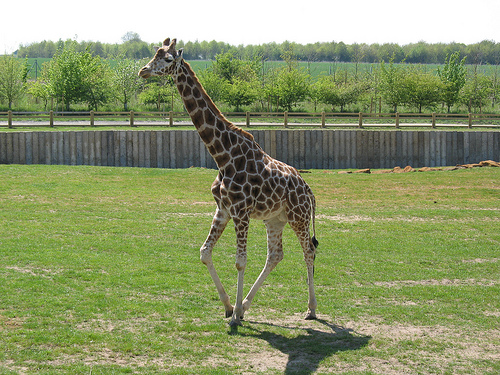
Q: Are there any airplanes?
A: No, there are no airplanes.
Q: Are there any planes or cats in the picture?
A: No, there are no planes or cats.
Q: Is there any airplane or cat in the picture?
A: No, there are no airplanes or cats.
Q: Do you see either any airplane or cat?
A: No, there are no airplanes or cats.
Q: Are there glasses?
A: No, there are no glasses.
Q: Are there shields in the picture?
A: No, there are no shields.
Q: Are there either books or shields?
A: No, there are no shields or books.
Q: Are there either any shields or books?
A: No, there are no shields or books.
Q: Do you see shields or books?
A: No, there are no shields or books.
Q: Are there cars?
A: No, there are no cars.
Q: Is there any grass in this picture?
A: Yes, there is grass.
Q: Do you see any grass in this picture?
A: Yes, there is grass.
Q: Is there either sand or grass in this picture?
A: Yes, there is grass.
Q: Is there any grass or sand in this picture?
A: Yes, there is grass.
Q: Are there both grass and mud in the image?
A: No, there is grass but no mud.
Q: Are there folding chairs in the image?
A: No, there are no folding chairs.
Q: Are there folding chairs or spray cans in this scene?
A: No, there are no folding chairs or spray cans.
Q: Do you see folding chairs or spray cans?
A: No, there are no folding chairs or spray cans.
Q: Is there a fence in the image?
A: Yes, there is a fence.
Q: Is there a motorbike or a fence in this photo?
A: Yes, there is a fence.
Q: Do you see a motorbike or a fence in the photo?
A: Yes, there is a fence.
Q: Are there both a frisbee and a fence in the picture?
A: No, there is a fence but no frisbees.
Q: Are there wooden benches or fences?
A: Yes, there is a wood fence.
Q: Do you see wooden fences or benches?
A: Yes, there is a wood fence.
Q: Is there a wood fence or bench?
A: Yes, there is a wood fence.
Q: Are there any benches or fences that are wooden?
A: Yes, the fence is wooden.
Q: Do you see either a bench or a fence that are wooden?
A: Yes, the fence is wooden.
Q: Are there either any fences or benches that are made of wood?
A: Yes, the fence is made of wood.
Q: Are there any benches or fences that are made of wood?
A: Yes, the fence is made of wood.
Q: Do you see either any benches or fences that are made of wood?
A: Yes, the fence is made of wood.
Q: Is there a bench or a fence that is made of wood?
A: Yes, the fence is made of wood.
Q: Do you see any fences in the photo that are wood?
A: Yes, there is a wood fence.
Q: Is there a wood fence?
A: Yes, there is a wood fence.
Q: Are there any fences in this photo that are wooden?
A: Yes, there is a fence that is wooden.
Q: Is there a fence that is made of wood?
A: Yes, there is a fence that is made of wood.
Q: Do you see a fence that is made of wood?
A: Yes, there is a fence that is made of wood.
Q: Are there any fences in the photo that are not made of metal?
A: Yes, there is a fence that is made of wood.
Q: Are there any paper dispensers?
A: No, there are no paper dispensers.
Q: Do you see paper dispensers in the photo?
A: No, there are no paper dispensers.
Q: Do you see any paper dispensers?
A: No, there are no paper dispensers.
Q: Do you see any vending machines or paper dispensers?
A: No, there are no paper dispensers or vending machines.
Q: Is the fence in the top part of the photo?
A: Yes, the fence is in the top of the image.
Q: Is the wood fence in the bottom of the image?
A: No, the fence is in the top of the image.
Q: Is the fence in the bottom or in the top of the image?
A: The fence is in the top of the image.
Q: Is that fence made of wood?
A: Yes, the fence is made of wood.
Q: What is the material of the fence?
A: The fence is made of wood.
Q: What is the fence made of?
A: The fence is made of wood.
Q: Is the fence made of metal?
A: No, the fence is made of wood.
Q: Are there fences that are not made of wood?
A: No, there is a fence but it is made of wood.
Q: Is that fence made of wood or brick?
A: The fence is made of wood.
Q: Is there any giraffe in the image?
A: Yes, there is a giraffe.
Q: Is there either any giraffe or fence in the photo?
A: Yes, there is a giraffe.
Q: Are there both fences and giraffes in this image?
A: Yes, there are both a giraffe and a fence.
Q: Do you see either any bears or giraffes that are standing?
A: Yes, the giraffe is standing.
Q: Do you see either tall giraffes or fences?
A: Yes, there is a tall giraffe.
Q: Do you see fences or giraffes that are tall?
A: Yes, the giraffe is tall.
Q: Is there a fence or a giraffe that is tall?
A: Yes, the giraffe is tall.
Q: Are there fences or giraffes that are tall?
A: Yes, the giraffe is tall.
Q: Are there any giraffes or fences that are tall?
A: Yes, the giraffe is tall.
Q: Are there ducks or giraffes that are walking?
A: Yes, the giraffe is walking.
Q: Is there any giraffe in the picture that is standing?
A: Yes, there is a giraffe that is standing.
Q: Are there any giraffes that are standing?
A: Yes, there is a giraffe that is standing.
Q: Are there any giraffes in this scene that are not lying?
A: Yes, there is a giraffe that is standing.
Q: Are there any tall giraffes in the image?
A: Yes, there is a tall giraffe.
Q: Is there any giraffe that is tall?
A: Yes, there is a giraffe that is tall.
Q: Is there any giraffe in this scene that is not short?
A: Yes, there is a tall giraffe.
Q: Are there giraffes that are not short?
A: Yes, there is a tall giraffe.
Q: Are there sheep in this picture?
A: No, there are no sheep.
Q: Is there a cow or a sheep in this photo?
A: No, there are no sheep or cows.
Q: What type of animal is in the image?
A: The animal is a giraffe.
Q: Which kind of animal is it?
A: The animal is a giraffe.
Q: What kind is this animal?
A: This is a giraffe.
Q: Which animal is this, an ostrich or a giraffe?
A: This is a giraffe.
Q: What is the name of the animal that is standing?
A: The animal is a giraffe.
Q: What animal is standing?
A: The animal is a giraffe.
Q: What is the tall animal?
A: The animal is a giraffe.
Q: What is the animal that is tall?
A: The animal is a giraffe.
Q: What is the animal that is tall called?
A: The animal is a giraffe.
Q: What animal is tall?
A: The animal is a giraffe.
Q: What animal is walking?
A: The animal is a giraffe.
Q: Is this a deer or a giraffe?
A: This is a giraffe.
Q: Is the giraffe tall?
A: Yes, the giraffe is tall.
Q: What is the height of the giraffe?
A: The giraffe is tall.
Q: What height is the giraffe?
A: The giraffe is tall.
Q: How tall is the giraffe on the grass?
A: The giraffe is tall.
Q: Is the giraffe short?
A: No, the giraffe is tall.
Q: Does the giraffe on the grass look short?
A: No, the giraffe is tall.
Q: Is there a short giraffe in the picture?
A: No, there is a giraffe but it is tall.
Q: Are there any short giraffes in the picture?
A: No, there is a giraffe but it is tall.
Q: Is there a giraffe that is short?
A: No, there is a giraffe but it is tall.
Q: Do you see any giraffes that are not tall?
A: No, there is a giraffe but it is tall.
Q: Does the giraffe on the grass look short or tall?
A: The giraffe is tall.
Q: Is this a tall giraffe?
A: Yes, this is a tall giraffe.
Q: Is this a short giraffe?
A: No, this is a tall giraffe.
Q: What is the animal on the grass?
A: The animal is a giraffe.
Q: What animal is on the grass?
A: The animal is a giraffe.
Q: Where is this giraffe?
A: The giraffe is on the grass.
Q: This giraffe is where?
A: The giraffe is on the grass.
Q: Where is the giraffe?
A: The giraffe is on the grass.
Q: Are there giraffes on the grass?
A: Yes, there is a giraffe on the grass.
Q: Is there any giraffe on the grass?
A: Yes, there is a giraffe on the grass.